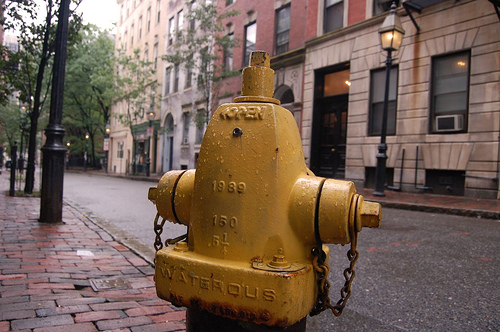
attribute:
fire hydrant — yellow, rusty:
[143, 46, 387, 330]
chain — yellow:
[302, 234, 372, 321]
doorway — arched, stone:
[158, 103, 179, 175]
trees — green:
[67, 18, 162, 170]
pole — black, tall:
[38, 12, 94, 258]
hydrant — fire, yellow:
[119, 46, 390, 318]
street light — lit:
[368, 0, 406, 197]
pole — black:
[365, 51, 407, 158]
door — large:
[307, 66, 364, 187]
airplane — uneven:
[9, 230, 109, 320]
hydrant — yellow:
[123, 83, 419, 317]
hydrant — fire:
[126, 27, 347, 291]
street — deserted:
[34, 167, 499, 329]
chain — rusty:
[298, 221, 378, 328]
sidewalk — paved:
[23, 226, 110, 330]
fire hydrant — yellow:
[221, 46, 291, 107]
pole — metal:
[38, 3, 75, 226]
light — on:
[379, 4, 406, 54]